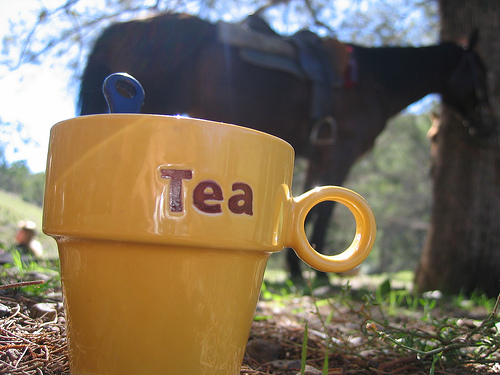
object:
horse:
[70, 9, 500, 287]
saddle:
[233, 15, 324, 42]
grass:
[0, 240, 500, 374]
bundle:
[0, 300, 60, 333]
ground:
[0, 241, 498, 375]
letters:
[159, 166, 194, 213]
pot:
[39, 113, 384, 375]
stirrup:
[306, 113, 340, 147]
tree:
[0, 0, 500, 301]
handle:
[102, 72, 148, 113]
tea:
[156, 167, 255, 216]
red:
[194, 191, 203, 201]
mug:
[35, 112, 382, 374]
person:
[0, 221, 46, 261]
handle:
[293, 183, 378, 276]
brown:
[173, 175, 180, 184]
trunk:
[409, 0, 500, 290]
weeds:
[238, 325, 500, 374]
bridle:
[465, 51, 495, 133]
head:
[438, 19, 499, 149]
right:
[251, 0, 500, 375]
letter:
[190, 180, 227, 216]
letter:
[226, 181, 255, 216]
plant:
[297, 316, 311, 374]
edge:
[0, 0, 440, 94]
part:
[4, 0, 353, 93]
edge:
[301, 199, 368, 258]